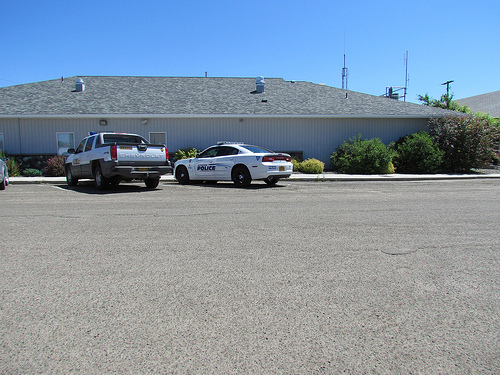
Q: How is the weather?
A: It is clear.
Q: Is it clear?
A: Yes, it is clear.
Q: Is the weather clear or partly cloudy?
A: It is clear.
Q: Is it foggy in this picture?
A: No, it is clear.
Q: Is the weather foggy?
A: No, it is clear.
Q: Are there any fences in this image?
A: No, there are no fences.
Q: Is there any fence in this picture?
A: No, there are no fences.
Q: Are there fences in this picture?
A: No, there are no fences.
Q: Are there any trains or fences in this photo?
A: No, there are no fences or trains.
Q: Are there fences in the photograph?
A: No, there are no fences.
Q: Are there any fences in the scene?
A: No, there are no fences.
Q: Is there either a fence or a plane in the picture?
A: No, there are no fences or airplanes.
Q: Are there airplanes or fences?
A: No, there are no fences or airplanes.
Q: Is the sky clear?
A: Yes, the sky is clear.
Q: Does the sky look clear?
A: Yes, the sky is clear.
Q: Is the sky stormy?
A: No, the sky is clear.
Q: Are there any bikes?
A: No, there are no bikes.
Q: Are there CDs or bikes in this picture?
A: No, there are no bikes or cds.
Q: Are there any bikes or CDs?
A: No, there are no bikes or cds.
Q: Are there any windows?
A: Yes, there is a window.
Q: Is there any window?
A: Yes, there is a window.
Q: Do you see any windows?
A: Yes, there is a window.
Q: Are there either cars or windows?
A: Yes, there is a window.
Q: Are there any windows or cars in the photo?
A: Yes, there is a window.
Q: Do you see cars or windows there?
A: Yes, there is a window.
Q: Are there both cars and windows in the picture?
A: Yes, there are both a window and a car.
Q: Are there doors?
A: No, there are no doors.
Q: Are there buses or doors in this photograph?
A: No, there are no doors or buses.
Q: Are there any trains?
A: No, there are no trains.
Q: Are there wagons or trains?
A: No, there are no trains or wagons.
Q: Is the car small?
A: Yes, the car is small.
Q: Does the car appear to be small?
A: Yes, the car is small.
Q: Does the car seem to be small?
A: Yes, the car is small.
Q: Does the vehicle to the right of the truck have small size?
A: Yes, the car is small.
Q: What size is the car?
A: The car is small.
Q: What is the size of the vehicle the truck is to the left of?
A: The car is small.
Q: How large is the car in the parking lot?
A: The car is small.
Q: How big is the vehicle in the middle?
A: The car is small.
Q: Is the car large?
A: No, the car is small.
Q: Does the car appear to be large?
A: No, the car is small.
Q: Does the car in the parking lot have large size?
A: No, the car is small.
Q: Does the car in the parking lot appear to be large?
A: No, the car is small.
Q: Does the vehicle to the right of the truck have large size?
A: No, the car is small.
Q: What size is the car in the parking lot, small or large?
A: The car is small.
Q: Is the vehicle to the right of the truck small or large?
A: The car is small.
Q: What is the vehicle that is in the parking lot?
A: The vehicle is a car.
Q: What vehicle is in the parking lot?
A: The vehicle is a car.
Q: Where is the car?
A: The car is in the parking lot.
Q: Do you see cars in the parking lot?
A: Yes, there is a car in the parking lot.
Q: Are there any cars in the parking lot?
A: Yes, there is a car in the parking lot.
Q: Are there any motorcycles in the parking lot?
A: No, there is a car in the parking lot.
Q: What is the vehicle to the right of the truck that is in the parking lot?
A: The vehicle is a car.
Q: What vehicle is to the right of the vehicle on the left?
A: The vehicle is a car.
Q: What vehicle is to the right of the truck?
A: The vehicle is a car.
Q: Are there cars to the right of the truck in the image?
A: Yes, there is a car to the right of the truck.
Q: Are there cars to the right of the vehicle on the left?
A: Yes, there is a car to the right of the truck.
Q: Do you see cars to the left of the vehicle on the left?
A: No, the car is to the right of the truck.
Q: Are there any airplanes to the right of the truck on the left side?
A: No, there is a car to the right of the truck.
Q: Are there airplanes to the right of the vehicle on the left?
A: No, there is a car to the right of the truck.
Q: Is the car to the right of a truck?
A: Yes, the car is to the right of a truck.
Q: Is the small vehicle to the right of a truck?
A: Yes, the car is to the right of a truck.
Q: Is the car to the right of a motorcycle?
A: No, the car is to the right of a truck.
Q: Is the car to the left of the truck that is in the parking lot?
A: No, the car is to the right of the truck.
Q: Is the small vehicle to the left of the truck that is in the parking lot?
A: No, the car is to the right of the truck.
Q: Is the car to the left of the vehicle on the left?
A: No, the car is to the right of the truck.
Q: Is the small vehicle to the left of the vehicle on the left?
A: No, the car is to the right of the truck.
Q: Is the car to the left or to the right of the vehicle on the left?
A: The car is to the right of the truck.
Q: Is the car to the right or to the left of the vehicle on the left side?
A: The car is to the right of the truck.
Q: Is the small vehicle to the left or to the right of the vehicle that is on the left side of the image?
A: The car is to the right of the truck.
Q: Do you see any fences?
A: No, there are no fences.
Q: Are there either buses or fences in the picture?
A: No, there are no fences or buses.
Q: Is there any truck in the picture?
A: Yes, there is a truck.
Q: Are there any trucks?
A: Yes, there is a truck.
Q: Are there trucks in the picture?
A: Yes, there is a truck.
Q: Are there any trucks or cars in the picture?
A: Yes, there is a truck.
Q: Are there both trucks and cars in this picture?
A: Yes, there are both a truck and cars.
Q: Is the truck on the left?
A: Yes, the truck is on the left of the image.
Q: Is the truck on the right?
A: No, the truck is on the left of the image.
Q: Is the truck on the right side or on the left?
A: The truck is on the left of the image.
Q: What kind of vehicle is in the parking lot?
A: The vehicle is a truck.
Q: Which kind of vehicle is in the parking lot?
A: The vehicle is a truck.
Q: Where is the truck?
A: The truck is in the parking lot.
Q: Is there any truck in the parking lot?
A: Yes, there is a truck in the parking lot.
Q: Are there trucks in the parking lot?
A: Yes, there is a truck in the parking lot.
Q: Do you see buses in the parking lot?
A: No, there is a truck in the parking lot.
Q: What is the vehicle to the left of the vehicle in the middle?
A: The vehicle is a truck.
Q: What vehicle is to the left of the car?
A: The vehicle is a truck.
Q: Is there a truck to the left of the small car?
A: Yes, there is a truck to the left of the car.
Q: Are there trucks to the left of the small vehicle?
A: Yes, there is a truck to the left of the car.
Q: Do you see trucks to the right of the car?
A: No, the truck is to the left of the car.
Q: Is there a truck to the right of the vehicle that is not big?
A: No, the truck is to the left of the car.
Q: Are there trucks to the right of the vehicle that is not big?
A: No, the truck is to the left of the car.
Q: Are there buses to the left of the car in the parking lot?
A: No, there is a truck to the left of the car.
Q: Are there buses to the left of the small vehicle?
A: No, there is a truck to the left of the car.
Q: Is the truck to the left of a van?
A: No, the truck is to the left of the car.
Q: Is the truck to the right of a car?
A: No, the truck is to the left of a car.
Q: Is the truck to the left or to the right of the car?
A: The truck is to the left of the car.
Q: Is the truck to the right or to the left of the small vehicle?
A: The truck is to the left of the car.